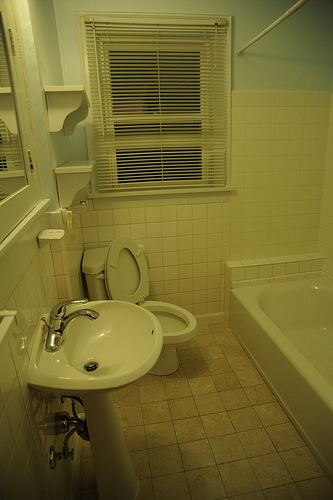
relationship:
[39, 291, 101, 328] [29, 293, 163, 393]
faucet on sink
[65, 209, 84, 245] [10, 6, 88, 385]
towel holder on wall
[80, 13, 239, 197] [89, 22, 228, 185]
window with blinds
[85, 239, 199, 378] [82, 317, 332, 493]
toilet on floor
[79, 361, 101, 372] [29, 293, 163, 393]
drain in sink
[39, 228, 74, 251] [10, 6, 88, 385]
soap dish on wall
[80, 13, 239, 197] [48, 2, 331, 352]
window on wall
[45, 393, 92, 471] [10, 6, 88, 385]
plumbing attached to wall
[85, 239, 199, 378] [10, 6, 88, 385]
toilet against wall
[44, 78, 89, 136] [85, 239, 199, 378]
shelf above toilet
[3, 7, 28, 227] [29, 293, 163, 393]
mirror above sink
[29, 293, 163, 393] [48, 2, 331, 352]
sink on wall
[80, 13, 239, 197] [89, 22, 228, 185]
window has blinds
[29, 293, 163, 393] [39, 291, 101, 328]
sink with faucet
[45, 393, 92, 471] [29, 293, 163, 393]
plumbing behind sink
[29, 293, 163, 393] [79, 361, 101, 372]
sink has a drain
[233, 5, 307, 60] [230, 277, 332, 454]
shower curtain rod over bathtub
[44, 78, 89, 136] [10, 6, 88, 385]
shelf on wall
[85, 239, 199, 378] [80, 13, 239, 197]
toilet next to window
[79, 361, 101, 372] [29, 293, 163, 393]
drain of sink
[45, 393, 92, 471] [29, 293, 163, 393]
plumbing under sink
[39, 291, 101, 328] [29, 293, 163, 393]
faucet for sink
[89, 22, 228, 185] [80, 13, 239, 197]
blinds on window